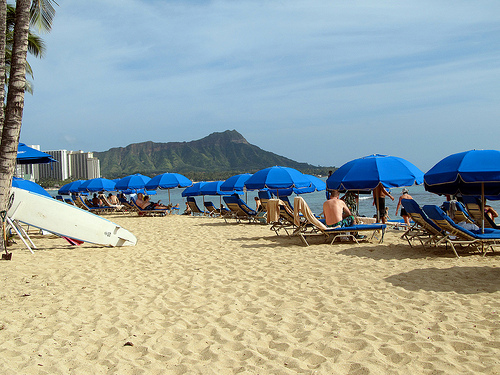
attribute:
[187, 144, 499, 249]
open umbrellas — blue, large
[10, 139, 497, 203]
umbrellas — blue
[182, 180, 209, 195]
beach umbrella — large, bright, blue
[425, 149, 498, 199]
umbrella — blue 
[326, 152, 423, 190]
umbrella — blue 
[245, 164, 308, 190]
umbrella — blue 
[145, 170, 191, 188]
umbrella — blue 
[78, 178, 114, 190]
umbrella — blue 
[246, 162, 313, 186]
umbrella — blue 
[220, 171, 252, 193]
umbrella — blue 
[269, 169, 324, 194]
umbrella — blue 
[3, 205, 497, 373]
beach — blue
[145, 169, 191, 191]
umbrella — large, blue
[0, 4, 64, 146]
palm trees — brown, green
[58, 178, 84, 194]
umbrella — blue 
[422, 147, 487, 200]
umbrella — blue 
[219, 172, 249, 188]
umbrella — blue 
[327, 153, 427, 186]
umbrella — blue 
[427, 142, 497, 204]
umbrella — blue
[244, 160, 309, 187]
umbrella — blue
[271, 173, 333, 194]
umbrella — blue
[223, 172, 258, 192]
umbrella — blue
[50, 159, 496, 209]
umbrellas — blue, large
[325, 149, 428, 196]
umbrella — large, bright, blue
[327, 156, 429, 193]
umbrella — large , bright, blue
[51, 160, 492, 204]
umbrellas — blue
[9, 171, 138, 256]
surfboard — white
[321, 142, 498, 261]
umbrellas — blue 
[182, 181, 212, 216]
umbrella — blue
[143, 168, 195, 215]
umbrella — large, bright, blue, beach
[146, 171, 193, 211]
umbrella — large, blue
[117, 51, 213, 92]
clouds — hazy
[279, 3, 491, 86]
sky — blue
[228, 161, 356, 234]
umbrella — large, blue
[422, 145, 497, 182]
blue umbrella — blue 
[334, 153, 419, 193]
blue umbrella — blue 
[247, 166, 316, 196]
blue umbrella — blue 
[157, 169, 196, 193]
blue umbrella — blue 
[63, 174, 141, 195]
blue umbrella — blue 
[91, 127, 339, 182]
mountains — in the distance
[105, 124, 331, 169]
mountain — green, brown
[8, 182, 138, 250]
surfboard — white, blue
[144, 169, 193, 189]
umbrella — large